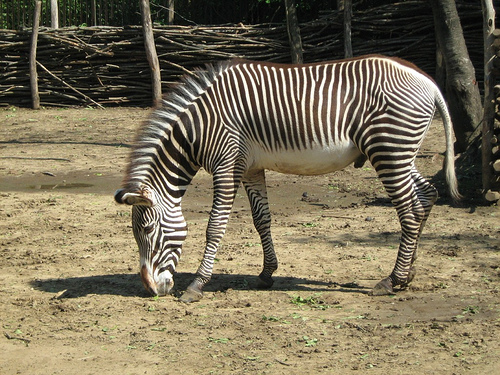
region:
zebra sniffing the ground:
[102, 157, 208, 329]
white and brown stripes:
[68, 35, 441, 340]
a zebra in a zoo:
[33, 8, 476, 320]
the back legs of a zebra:
[364, 163, 439, 299]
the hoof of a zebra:
[368, 273, 396, 303]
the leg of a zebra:
[246, 177, 285, 289]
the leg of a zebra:
[182, 185, 239, 301]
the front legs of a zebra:
[192, 173, 294, 291]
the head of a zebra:
[102, 180, 192, 300]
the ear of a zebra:
[119, 185, 161, 210]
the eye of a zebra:
[137, 215, 156, 234]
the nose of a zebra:
[141, 261, 168, 296]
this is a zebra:
[128, 69, 448, 336]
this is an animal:
[116, 71, 248, 207]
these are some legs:
[152, 112, 379, 310]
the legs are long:
[125, 201, 285, 322]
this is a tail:
[386, 81, 494, 136]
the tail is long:
[421, 108, 473, 199]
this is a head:
[99, 172, 224, 340]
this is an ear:
[121, 176, 142, 206]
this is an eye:
[87, 206, 167, 248]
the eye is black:
[125, 206, 161, 256]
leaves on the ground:
[287, 290, 344, 328]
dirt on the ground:
[18, 333, 185, 373]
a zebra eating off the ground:
[117, 55, 462, 301]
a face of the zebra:
[118, 185, 188, 294]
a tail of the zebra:
[433, 100, 463, 199]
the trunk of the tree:
[438, 8, 488, 173]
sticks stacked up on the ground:
[23, 30, 164, 102]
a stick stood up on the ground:
[141, 5, 165, 106]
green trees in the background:
[7, 5, 173, 23]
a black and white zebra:
[115, 53, 461, 298]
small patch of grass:
[291, 293, 327, 310]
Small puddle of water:
[28, 179, 96, 192]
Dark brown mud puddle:
[278, 188, 334, 205]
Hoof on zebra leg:
[372, 274, 410, 298]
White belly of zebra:
[268, 151, 348, 173]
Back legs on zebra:
[371, 151, 422, 296]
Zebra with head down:
[113, 185, 189, 296]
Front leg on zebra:
[196, 173, 223, 300]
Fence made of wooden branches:
[40, 31, 144, 107]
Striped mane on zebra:
[138, 122, 161, 156]